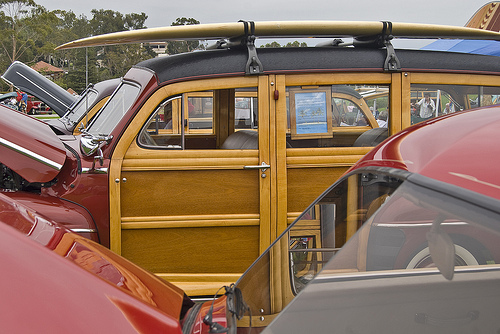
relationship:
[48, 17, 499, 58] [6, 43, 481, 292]
surfboard on top of car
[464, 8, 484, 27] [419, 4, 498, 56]
fin on surfboard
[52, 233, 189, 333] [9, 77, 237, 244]
hood of car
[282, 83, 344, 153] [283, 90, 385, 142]
sign on window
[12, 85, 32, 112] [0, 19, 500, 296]
people looking at car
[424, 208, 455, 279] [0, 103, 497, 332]
mirror in car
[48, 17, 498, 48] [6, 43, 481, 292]
surfboard on top of car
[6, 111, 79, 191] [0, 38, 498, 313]
hood on car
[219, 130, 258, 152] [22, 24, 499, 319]
backrest in car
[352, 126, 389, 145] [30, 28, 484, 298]
backrest in car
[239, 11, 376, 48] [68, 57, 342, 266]
surfboard on top of car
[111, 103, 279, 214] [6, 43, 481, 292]
wooden doors of car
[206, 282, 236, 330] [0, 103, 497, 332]
windshield wiper on car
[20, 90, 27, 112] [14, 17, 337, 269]
people standing away from car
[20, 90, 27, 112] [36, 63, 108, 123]
people standing away from car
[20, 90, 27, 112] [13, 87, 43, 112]
people standing away from car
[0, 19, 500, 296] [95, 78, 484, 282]
car with exterior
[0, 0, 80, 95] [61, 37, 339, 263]
tree behind car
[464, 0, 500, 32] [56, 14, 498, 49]
fin of surfboard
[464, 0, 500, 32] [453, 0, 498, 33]
fin with carving